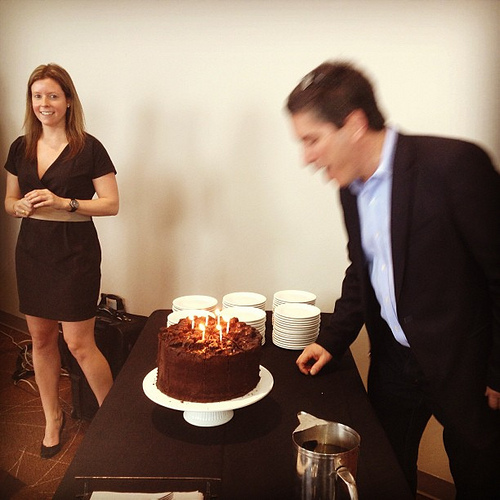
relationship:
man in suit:
[285, 61, 499, 498] [295, 155, 479, 486]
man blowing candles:
[285, 61, 499, 498] [187, 312, 231, 341]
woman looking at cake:
[0, 65, 118, 465] [141, 311, 273, 429]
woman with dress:
[0, 65, 118, 465] [4, 133, 133, 332]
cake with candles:
[160, 318, 271, 397] [185, 313, 231, 345]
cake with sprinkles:
[160, 318, 271, 397] [158, 318, 261, 358]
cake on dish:
[160, 318, 271, 397] [141, 363, 275, 428]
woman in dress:
[0, 65, 118, 465] [6, 130, 124, 329]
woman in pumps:
[0, 65, 118, 465] [39, 402, 69, 458]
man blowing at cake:
[285, 61, 499, 498] [155, 316, 261, 402]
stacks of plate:
[169, 288, 323, 349] [162, 286, 324, 352]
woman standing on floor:
[0, 65, 118, 465] [15, 393, 27, 472]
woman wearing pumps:
[3, 65, 118, 460] [39, 412, 66, 458]